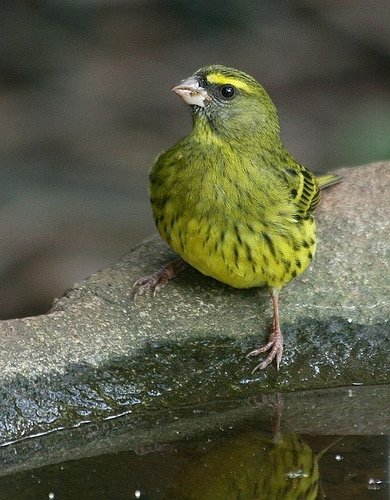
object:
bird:
[132, 64, 345, 374]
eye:
[217, 81, 237, 99]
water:
[0, 384, 389, 497]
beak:
[170, 73, 206, 111]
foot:
[245, 328, 284, 374]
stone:
[1, 161, 390, 446]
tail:
[310, 164, 348, 191]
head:
[172, 62, 280, 143]